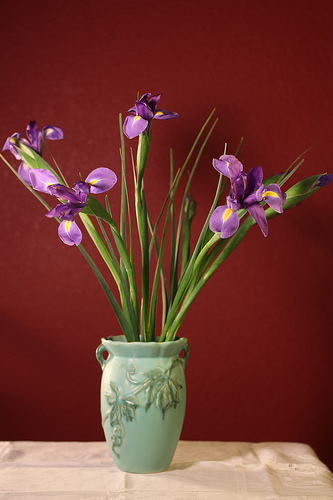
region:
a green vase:
[97, 339, 207, 483]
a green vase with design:
[87, 333, 202, 482]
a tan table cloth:
[195, 439, 319, 497]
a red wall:
[219, 300, 331, 427]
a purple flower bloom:
[200, 149, 283, 244]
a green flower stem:
[120, 140, 178, 333]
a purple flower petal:
[54, 222, 90, 249]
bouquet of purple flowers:
[4, 89, 328, 489]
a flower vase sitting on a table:
[40, 316, 255, 498]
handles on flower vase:
[89, 343, 113, 366]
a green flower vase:
[91, 328, 205, 470]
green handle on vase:
[88, 339, 107, 361]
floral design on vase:
[102, 360, 179, 453]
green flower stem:
[131, 149, 148, 335]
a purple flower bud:
[109, 84, 177, 140]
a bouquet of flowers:
[5, 87, 323, 337]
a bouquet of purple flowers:
[0, 77, 332, 332]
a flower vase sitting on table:
[12, 90, 307, 482]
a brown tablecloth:
[190, 434, 320, 496]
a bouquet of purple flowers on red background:
[5, 91, 314, 429]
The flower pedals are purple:
[0, 89, 304, 251]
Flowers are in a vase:
[4, 88, 283, 475]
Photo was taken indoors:
[2, 4, 330, 495]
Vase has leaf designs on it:
[101, 361, 183, 425]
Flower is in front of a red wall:
[9, 49, 325, 436]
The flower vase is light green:
[84, 330, 201, 480]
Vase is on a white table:
[1, 424, 328, 498]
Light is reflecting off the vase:
[83, 354, 124, 431]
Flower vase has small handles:
[91, 337, 190, 366]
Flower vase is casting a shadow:
[153, 415, 264, 477]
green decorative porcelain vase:
[95, 335, 191, 473]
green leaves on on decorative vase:
[104, 357, 182, 459]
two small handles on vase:
[95, 344, 191, 364]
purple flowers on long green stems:
[0, 90, 331, 340]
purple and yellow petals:
[209, 154, 282, 238]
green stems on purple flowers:
[78, 248, 235, 334]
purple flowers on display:
[0, 0, 331, 498]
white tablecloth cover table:
[0, 441, 332, 498]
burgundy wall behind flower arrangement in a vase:
[216, 287, 321, 394]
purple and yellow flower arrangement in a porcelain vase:
[0, 89, 331, 474]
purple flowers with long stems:
[0, 77, 284, 439]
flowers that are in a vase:
[12, 92, 264, 445]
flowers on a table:
[3, 68, 263, 497]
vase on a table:
[71, 313, 260, 496]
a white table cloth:
[7, 389, 329, 498]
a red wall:
[13, 85, 328, 394]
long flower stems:
[23, 158, 248, 344]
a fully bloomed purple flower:
[203, 139, 297, 272]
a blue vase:
[47, 319, 224, 495]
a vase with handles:
[74, 302, 245, 497]